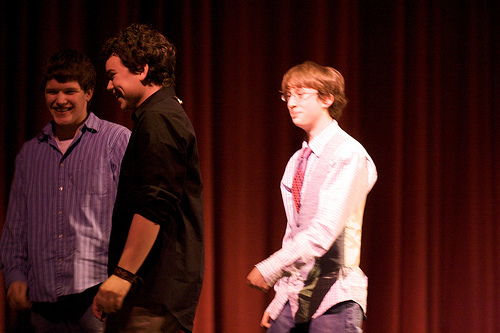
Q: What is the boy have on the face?
A: Glasses.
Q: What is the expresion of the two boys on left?
A: Smiling.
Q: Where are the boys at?
A: A stage.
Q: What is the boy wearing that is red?
A: A tie.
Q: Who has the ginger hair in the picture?
A: The boy with glasses.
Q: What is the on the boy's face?
A: Glasses.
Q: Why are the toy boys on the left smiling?
A: They are laughing.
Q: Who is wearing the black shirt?
A: The boy with curly hair.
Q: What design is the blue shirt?
A: Button down.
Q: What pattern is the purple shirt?
A: Stripped.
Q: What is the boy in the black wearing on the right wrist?
A: A leather bracelet.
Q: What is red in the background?
A: Curtains.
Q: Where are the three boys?
A: In front of curtain.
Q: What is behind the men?
A: A curtain.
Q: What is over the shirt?
A: A vest.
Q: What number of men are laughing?
A: Two.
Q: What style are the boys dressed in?
A: Casual.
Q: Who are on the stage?
A: Young Men.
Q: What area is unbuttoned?
A: Top collar.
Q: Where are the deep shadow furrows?
A: On the curtain.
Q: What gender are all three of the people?
A: Male.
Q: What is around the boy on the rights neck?
A: A tie.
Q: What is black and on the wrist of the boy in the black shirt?
A: A bracelet.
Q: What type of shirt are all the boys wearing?
A: Collared shirt.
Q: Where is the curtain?
A: Behind the boys.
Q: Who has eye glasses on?
A: Boy in the tie.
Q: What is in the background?
A: A curtain.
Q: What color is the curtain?
A: A dark shade of red.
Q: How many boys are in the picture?
A: Three.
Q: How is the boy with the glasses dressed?
A: Shirt and tie, vest and pants.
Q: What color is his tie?
A: Red and black.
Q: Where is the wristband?
A: On a boy's left wrist.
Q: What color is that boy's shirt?
A: Black.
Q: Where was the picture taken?
A: On a stage.